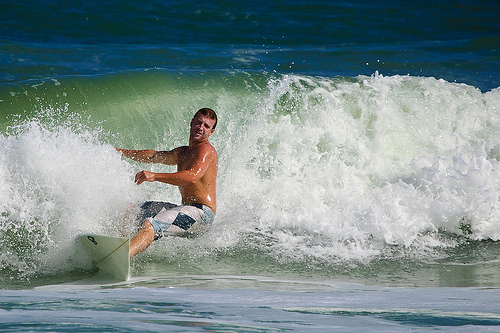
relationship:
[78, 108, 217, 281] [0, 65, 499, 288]
man in wave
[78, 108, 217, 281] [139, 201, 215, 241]
man wears short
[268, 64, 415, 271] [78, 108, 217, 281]
water in man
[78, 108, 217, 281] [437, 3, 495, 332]
man leaning right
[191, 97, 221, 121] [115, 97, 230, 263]
hair on man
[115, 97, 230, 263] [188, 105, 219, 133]
man has hair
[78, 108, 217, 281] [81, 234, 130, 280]
man on board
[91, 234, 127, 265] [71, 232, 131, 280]
stripe on board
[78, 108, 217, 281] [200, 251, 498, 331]
man surfing in water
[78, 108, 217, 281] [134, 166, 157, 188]
man has hand